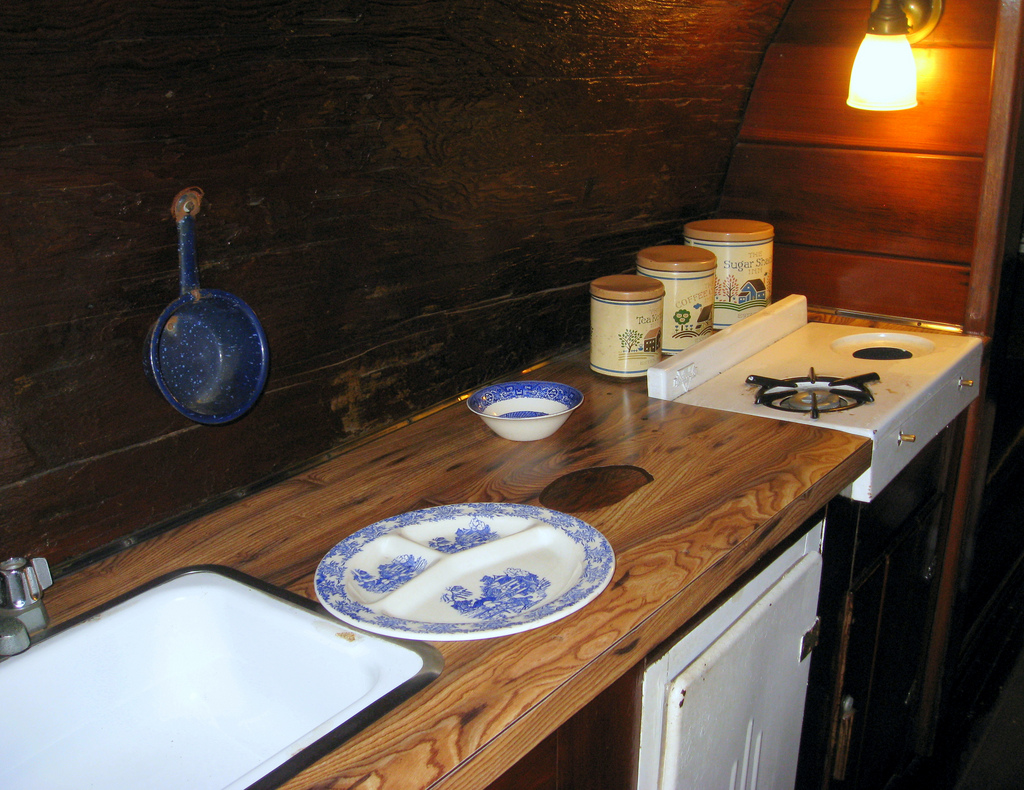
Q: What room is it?
A: It is a kitchen.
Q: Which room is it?
A: It is a kitchen.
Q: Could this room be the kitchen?
A: Yes, it is the kitchen.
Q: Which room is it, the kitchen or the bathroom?
A: It is the kitchen.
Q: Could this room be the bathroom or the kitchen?
A: It is the kitchen.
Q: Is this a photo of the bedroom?
A: No, the picture is showing the kitchen.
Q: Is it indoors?
A: Yes, it is indoors.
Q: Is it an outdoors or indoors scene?
A: It is indoors.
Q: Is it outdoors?
A: No, it is indoors.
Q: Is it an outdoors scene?
A: No, it is indoors.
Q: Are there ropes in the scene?
A: No, there are no ropes.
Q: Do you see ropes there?
A: No, there are no ropes.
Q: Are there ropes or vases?
A: No, there are no ropes or vases.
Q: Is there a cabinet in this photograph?
A: Yes, there is a cabinet.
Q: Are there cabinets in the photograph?
A: Yes, there is a cabinet.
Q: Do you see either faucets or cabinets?
A: Yes, there is a cabinet.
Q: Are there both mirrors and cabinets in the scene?
A: No, there is a cabinet but no mirrors.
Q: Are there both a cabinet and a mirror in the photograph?
A: No, there is a cabinet but no mirrors.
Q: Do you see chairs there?
A: No, there are no chairs.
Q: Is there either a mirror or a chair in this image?
A: No, there are no chairs or mirrors.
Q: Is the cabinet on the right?
A: Yes, the cabinet is on the right of the image.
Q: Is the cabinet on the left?
A: No, the cabinet is on the right of the image.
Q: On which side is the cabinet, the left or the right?
A: The cabinet is on the right of the image.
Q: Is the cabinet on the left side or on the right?
A: The cabinet is on the right of the image.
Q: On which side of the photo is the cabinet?
A: The cabinet is on the right of the image.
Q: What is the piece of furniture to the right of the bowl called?
A: The piece of furniture is a cabinet.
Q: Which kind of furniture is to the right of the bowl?
A: The piece of furniture is a cabinet.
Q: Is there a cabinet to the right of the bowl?
A: Yes, there is a cabinet to the right of the bowl.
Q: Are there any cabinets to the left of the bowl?
A: No, the cabinet is to the right of the bowl.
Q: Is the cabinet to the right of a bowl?
A: Yes, the cabinet is to the right of a bowl.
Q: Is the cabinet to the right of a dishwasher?
A: No, the cabinet is to the right of a bowl.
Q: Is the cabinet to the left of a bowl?
A: No, the cabinet is to the right of a bowl.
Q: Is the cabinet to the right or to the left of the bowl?
A: The cabinet is to the right of the bowl.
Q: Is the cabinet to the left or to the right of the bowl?
A: The cabinet is to the right of the bowl.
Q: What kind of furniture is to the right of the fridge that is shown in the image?
A: The piece of furniture is a cabinet.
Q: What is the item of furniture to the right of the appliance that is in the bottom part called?
A: The piece of furniture is a cabinet.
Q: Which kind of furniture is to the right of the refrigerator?
A: The piece of furniture is a cabinet.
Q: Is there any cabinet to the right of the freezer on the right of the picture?
A: Yes, there is a cabinet to the right of the fridge.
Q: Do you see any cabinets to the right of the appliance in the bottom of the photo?
A: Yes, there is a cabinet to the right of the fridge.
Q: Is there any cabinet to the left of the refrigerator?
A: No, the cabinet is to the right of the refrigerator.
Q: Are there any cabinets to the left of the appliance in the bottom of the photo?
A: No, the cabinet is to the right of the refrigerator.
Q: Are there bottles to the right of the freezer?
A: No, there is a cabinet to the right of the freezer.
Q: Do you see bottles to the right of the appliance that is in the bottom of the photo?
A: No, there is a cabinet to the right of the freezer.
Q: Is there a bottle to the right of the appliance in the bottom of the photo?
A: No, there is a cabinet to the right of the freezer.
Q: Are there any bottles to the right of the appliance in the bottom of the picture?
A: No, there is a cabinet to the right of the freezer.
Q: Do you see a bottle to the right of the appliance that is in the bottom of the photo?
A: No, there is a cabinet to the right of the freezer.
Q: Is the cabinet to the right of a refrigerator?
A: Yes, the cabinet is to the right of a refrigerator.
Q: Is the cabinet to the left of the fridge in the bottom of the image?
A: No, the cabinet is to the right of the freezer.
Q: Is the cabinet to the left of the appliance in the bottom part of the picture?
A: No, the cabinet is to the right of the freezer.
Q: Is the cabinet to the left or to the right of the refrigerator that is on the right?
A: The cabinet is to the right of the refrigerator.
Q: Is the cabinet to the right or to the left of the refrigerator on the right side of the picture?
A: The cabinet is to the right of the refrigerator.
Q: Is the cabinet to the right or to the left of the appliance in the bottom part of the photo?
A: The cabinet is to the right of the refrigerator.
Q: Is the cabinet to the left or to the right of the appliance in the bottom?
A: The cabinet is to the right of the refrigerator.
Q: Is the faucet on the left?
A: Yes, the faucet is on the left of the image.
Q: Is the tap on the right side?
A: No, the tap is on the left of the image.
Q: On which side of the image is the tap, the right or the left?
A: The tap is on the left of the image.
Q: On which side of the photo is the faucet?
A: The faucet is on the left of the image.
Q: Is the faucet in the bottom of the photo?
A: Yes, the faucet is in the bottom of the image.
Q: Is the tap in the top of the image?
A: No, the tap is in the bottom of the image.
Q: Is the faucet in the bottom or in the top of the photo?
A: The faucet is in the bottom of the image.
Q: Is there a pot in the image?
A: Yes, there is a pot.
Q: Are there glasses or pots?
A: Yes, there is a pot.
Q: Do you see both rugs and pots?
A: No, there is a pot but no rugs.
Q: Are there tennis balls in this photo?
A: No, there are no tennis balls.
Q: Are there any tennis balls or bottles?
A: No, there are no tennis balls or bottles.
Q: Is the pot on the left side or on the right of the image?
A: The pot is on the left of the image.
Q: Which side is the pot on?
A: The pot is on the left of the image.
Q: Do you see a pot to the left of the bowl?
A: Yes, there is a pot to the left of the bowl.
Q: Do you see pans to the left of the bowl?
A: No, there is a pot to the left of the bowl.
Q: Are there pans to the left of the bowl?
A: No, there is a pot to the left of the bowl.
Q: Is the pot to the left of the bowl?
A: Yes, the pot is to the left of the bowl.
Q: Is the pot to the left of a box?
A: No, the pot is to the left of the bowl.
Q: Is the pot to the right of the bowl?
A: No, the pot is to the left of the bowl.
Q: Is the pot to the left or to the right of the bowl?
A: The pot is to the left of the bowl.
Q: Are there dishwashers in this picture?
A: No, there are no dishwashers.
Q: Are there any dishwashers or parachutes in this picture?
A: No, there are no dishwashers or parachutes.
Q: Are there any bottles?
A: No, there are no bottles.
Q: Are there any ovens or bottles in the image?
A: No, there are no bottles or ovens.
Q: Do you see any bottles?
A: No, there are no bottles.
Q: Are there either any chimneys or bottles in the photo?
A: No, there are no bottles or chimneys.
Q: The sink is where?
A: The sink is in the kitchen.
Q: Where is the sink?
A: The sink is in the kitchen.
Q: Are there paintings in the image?
A: No, there are no paintings.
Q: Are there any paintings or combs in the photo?
A: No, there are no paintings or combs.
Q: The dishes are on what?
A: The dishes are on the counter.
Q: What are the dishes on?
A: The dishes are on the counter.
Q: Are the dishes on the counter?
A: Yes, the dishes are on the counter.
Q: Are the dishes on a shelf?
A: No, the dishes are on the counter.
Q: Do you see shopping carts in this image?
A: No, there are no shopping carts.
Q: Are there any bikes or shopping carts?
A: No, there are no shopping carts or bikes.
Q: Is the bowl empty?
A: Yes, the bowl is empty.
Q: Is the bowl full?
A: No, the bowl is empty.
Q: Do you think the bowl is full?
A: No, the bowl is empty.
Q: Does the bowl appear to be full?
A: No, the bowl is empty.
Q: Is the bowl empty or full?
A: The bowl is empty.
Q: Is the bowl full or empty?
A: The bowl is empty.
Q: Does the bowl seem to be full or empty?
A: The bowl is empty.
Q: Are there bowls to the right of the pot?
A: Yes, there is a bowl to the right of the pot.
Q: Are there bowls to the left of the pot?
A: No, the bowl is to the right of the pot.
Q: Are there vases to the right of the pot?
A: No, there is a bowl to the right of the pot.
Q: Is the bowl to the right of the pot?
A: Yes, the bowl is to the right of the pot.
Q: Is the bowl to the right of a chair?
A: No, the bowl is to the right of the pot.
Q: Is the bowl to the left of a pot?
A: No, the bowl is to the right of a pot.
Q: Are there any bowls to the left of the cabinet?
A: Yes, there is a bowl to the left of the cabinet.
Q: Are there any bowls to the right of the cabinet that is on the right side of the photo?
A: No, the bowl is to the left of the cabinet.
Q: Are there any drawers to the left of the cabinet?
A: No, there is a bowl to the left of the cabinet.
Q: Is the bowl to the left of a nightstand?
A: No, the bowl is to the left of a cabinet.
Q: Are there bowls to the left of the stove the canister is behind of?
A: Yes, there is a bowl to the left of the stove.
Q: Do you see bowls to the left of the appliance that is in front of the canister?
A: Yes, there is a bowl to the left of the stove.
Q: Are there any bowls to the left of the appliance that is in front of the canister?
A: Yes, there is a bowl to the left of the stove.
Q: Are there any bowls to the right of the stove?
A: No, the bowl is to the left of the stove.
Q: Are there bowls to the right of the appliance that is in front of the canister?
A: No, the bowl is to the left of the stove.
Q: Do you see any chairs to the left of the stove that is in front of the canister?
A: No, there is a bowl to the left of the stove.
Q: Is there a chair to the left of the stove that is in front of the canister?
A: No, there is a bowl to the left of the stove.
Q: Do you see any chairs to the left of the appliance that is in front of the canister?
A: No, there is a bowl to the left of the stove.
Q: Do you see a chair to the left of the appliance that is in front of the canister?
A: No, there is a bowl to the left of the stove.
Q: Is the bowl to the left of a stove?
A: Yes, the bowl is to the left of a stove.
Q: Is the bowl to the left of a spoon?
A: No, the bowl is to the left of a stove.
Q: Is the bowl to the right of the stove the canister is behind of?
A: No, the bowl is to the left of the stove.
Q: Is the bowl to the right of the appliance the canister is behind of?
A: No, the bowl is to the left of the stove.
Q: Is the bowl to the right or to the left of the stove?
A: The bowl is to the left of the stove.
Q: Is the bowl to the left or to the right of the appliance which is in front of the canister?
A: The bowl is to the left of the stove.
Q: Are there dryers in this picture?
A: No, there are no dryers.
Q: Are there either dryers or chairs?
A: No, there are no dryers or chairs.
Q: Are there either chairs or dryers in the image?
A: No, there are no dryers or chairs.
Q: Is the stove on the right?
A: Yes, the stove is on the right of the image.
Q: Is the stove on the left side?
A: No, the stove is on the right of the image.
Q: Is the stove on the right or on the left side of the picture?
A: The stove is on the right of the image.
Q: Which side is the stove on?
A: The stove is on the right of the image.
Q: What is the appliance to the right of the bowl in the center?
A: The appliance is a stove.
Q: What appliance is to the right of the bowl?
A: The appliance is a stove.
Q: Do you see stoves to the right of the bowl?
A: Yes, there is a stove to the right of the bowl.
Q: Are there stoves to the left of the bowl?
A: No, the stove is to the right of the bowl.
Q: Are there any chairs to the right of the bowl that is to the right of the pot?
A: No, there is a stove to the right of the bowl.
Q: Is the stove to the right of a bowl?
A: Yes, the stove is to the right of a bowl.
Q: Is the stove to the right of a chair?
A: No, the stove is to the right of a bowl.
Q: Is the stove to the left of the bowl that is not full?
A: No, the stove is to the right of the bowl.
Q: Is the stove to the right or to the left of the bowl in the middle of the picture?
A: The stove is to the right of the bowl.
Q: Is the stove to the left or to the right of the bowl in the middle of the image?
A: The stove is to the right of the bowl.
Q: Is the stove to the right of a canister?
A: Yes, the stove is to the right of a canister.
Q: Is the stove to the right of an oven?
A: No, the stove is to the right of a canister.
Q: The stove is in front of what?
A: The stove is in front of the canister.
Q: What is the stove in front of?
A: The stove is in front of the canister.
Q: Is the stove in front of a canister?
A: Yes, the stove is in front of a canister.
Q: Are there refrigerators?
A: Yes, there is a refrigerator.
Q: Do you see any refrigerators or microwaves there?
A: Yes, there is a refrigerator.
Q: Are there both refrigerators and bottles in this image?
A: No, there is a refrigerator but no bottles.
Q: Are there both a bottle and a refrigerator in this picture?
A: No, there is a refrigerator but no bottles.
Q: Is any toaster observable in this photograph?
A: No, there are no toasters.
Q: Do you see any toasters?
A: No, there are no toasters.